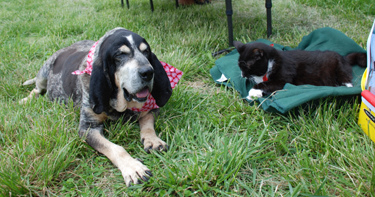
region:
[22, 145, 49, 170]
green grass on ground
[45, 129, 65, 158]
green grass on ground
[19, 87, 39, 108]
green grass on ground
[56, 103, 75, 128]
green grass on ground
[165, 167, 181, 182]
green grass on ground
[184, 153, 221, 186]
green grass on ground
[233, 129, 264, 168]
green grass on ground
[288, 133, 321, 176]
green grass on ground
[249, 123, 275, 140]
green grass on ground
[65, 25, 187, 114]
Pink handkerchief around dog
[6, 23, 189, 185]
black and white dog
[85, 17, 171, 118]
droopy face of dogs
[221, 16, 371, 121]
black and white cat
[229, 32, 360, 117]
cat on green blanket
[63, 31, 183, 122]
pink polka dot handkerchief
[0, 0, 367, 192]
vibrant green cut lawn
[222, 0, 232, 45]
black legs of table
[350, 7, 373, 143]
yellow and red object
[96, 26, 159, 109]
THIS IS THE DOGS HEAD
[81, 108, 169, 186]
THIS IS THE DOGS ARM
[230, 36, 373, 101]
THIS IS A CAT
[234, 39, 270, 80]
THIS IS A CAT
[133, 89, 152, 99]
THIS IS THE DOGS TONGUE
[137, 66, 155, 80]
THE DOGS BLACK NOSE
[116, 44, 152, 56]
THESE ARE THE DOGS EYES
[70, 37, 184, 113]
THIS IS A PINK SCARF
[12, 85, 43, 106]
THATS THE DOGS LEG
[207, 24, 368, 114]
THATS A GREEN BLANKET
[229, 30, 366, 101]
Black and white cat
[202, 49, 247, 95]
Folded green blanket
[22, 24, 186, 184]
Big black, brown and gray dog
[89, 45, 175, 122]
Big black floppy ears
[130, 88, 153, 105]
Dog's tongue is red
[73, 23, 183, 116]
Pink and white polka dot scarf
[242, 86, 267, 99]
Cat has two white front feet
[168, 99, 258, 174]
Tall green grass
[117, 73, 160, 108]
Dogs mouth is open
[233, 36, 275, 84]
Cat has red on it's neck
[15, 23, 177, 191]
A dog in the foreground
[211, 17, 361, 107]
A cat in the foreground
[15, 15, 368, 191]
A dog and a cat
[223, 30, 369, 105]
A side view of a cat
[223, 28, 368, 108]
The cat is black in color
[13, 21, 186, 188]
Dog is on the grass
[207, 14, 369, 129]
Cat is on a green cloth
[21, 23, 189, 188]
Dog's fur is black and tan in color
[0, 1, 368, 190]
Photo was taken in the daytime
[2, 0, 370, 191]
Photo was taken outdoors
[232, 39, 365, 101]
black and white haired cat on blanket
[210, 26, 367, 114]
small green fleece blanket on grass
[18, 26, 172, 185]
black, brown and white dog lays in grass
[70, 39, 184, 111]
red and pink bandanna on dog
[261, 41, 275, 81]
thin red ribbon on black cat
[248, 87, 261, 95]
furry white front left cat paw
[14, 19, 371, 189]
dog and cat in the grass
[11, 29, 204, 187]
dog with pink scarf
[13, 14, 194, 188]
dog with pink poka dotted scarf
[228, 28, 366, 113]
cat lying on green pad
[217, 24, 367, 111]
cat on green blanket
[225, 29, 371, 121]
black cat with white paws